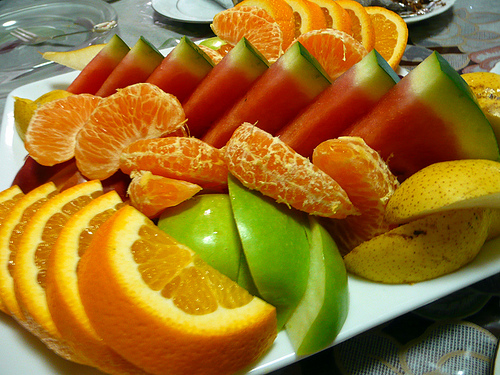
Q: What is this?
A: A fruit plate.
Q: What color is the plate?
A: White.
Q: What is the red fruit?
A: Watermelon.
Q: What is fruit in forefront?
A: Oranges.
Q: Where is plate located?
A: On a table.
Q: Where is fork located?
A: On clear plate.